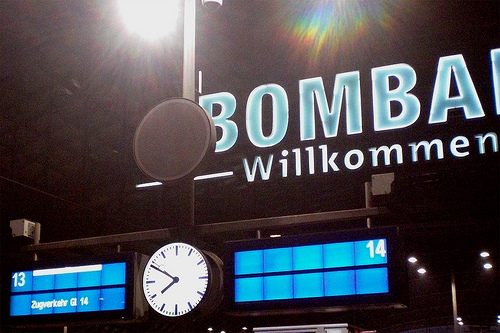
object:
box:
[6, 217, 37, 242]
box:
[368, 170, 399, 196]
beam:
[24, 205, 387, 253]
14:
[364, 239, 389, 259]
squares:
[234, 276, 265, 303]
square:
[262, 247, 293, 272]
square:
[291, 245, 324, 272]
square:
[323, 241, 356, 269]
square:
[354, 267, 390, 295]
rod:
[21, 204, 387, 257]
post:
[167, 181, 197, 228]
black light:
[128, 96, 219, 188]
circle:
[130, 97, 217, 185]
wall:
[8, 24, 145, 318]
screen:
[8, 261, 126, 317]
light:
[115, 0, 183, 42]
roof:
[0, 0, 500, 121]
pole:
[179, 0, 196, 110]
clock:
[138, 242, 218, 319]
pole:
[164, 4, 201, 331]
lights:
[354, 264, 390, 297]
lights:
[406, 257, 418, 263]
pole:
[161, 183, 200, 238]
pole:
[32, 223, 41, 262]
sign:
[9, 232, 416, 327]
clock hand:
[160, 280, 176, 293]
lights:
[417, 266, 428, 275]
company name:
[199, 48, 499, 180]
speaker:
[128, 96, 219, 190]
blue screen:
[7, 263, 127, 315]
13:
[6, 268, 36, 291]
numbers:
[145, 244, 204, 314]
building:
[3, 173, 399, 333]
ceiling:
[2, 0, 500, 68]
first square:
[10, 270, 33, 293]